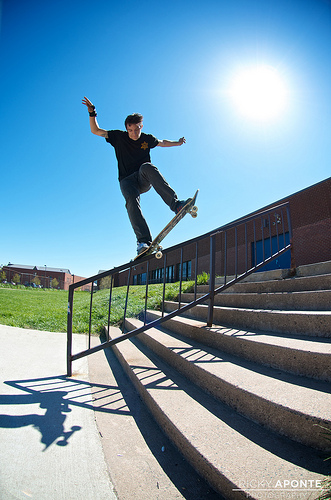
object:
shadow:
[0, 388, 82, 453]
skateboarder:
[79, 94, 191, 254]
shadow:
[128, 360, 189, 403]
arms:
[149, 135, 180, 150]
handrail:
[73, 271, 107, 288]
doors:
[249, 232, 290, 270]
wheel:
[155, 251, 162, 259]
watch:
[88, 111, 97, 117]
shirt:
[105, 128, 159, 179]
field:
[0, 286, 71, 326]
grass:
[49, 290, 57, 304]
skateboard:
[133, 189, 198, 264]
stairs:
[233, 328, 302, 375]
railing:
[68, 275, 242, 357]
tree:
[32, 277, 41, 288]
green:
[22, 303, 45, 311]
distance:
[3, 267, 66, 292]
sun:
[219, 64, 296, 128]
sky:
[64, 15, 156, 80]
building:
[230, 206, 322, 274]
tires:
[192, 211, 198, 217]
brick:
[315, 210, 319, 218]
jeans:
[116, 164, 182, 240]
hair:
[125, 112, 143, 131]